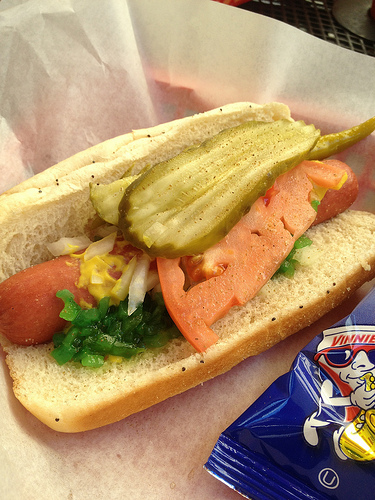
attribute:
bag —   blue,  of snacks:
[202, 285, 373, 498]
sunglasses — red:
[314, 343, 374, 367]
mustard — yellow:
[79, 252, 126, 303]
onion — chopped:
[126, 259, 153, 322]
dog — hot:
[76, 252, 130, 303]